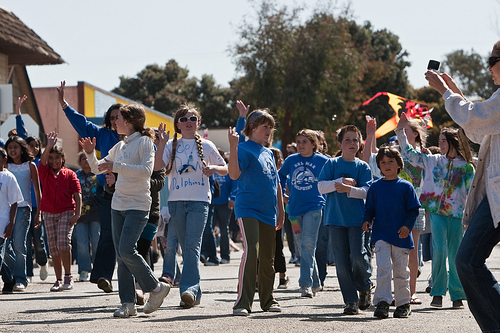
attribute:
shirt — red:
[44, 175, 71, 211]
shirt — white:
[170, 139, 227, 192]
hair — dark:
[380, 139, 405, 175]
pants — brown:
[233, 215, 278, 312]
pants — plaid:
[38, 208, 73, 255]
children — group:
[261, 97, 473, 306]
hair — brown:
[161, 101, 212, 176]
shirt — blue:
[235, 137, 281, 212]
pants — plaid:
[45, 200, 103, 254]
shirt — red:
[38, 169, 79, 211]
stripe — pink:
[233, 218, 252, 302]